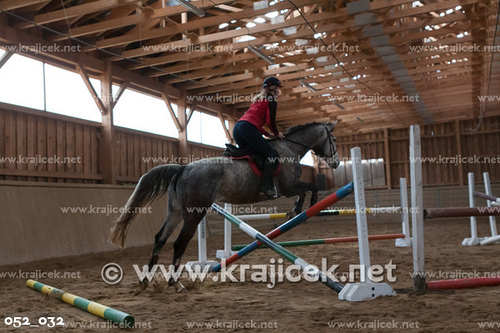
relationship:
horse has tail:
[110, 120, 341, 293] [102, 160, 182, 247]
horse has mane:
[110, 120, 341, 293] [286, 113, 333, 140]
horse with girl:
[74, 84, 387, 310] [232, 77, 283, 197]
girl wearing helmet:
[232, 77, 283, 197] [255, 71, 287, 89]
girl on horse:
[232, 77, 283, 197] [137, 125, 367, 255]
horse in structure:
[110, 120, 341, 293] [179, 187, 369, 287]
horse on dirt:
[110, 120, 341, 293] [194, 292, 272, 321]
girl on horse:
[232, 77, 283, 197] [72, 131, 340, 229]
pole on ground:
[65, 299, 131, 320] [174, 294, 246, 302]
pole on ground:
[425, 275, 458, 302] [383, 254, 468, 302]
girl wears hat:
[236, 83, 282, 177] [257, 70, 284, 89]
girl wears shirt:
[232, 77, 283, 197] [234, 86, 275, 136]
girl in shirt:
[232, 77, 283, 197] [227, 83, 270, 136]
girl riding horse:
[232, 77, 283, 197] [119, 137, 345, 217]